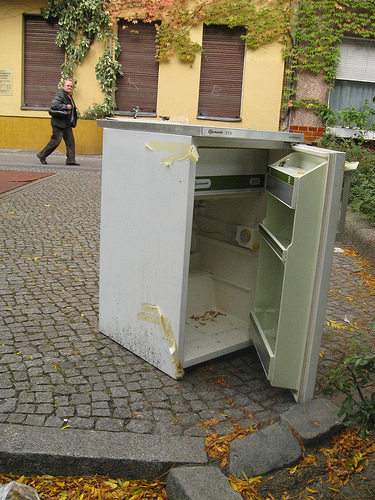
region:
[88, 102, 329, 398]
a white refridgerator on the sidewalk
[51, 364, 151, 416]
grey stone surface of the sidewalk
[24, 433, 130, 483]
grey stone curb of the sidewalk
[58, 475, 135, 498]
yellow dead fallen leaves on the street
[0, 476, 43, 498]
a clear plastic bag on the ground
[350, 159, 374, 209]
green plants growing next to the courtyard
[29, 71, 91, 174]
a man walking through the courtyard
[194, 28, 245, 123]
brown shades drawn over the window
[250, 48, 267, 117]
yellow stucco wall of a building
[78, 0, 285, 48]
plants growing on the side of the building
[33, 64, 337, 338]
a refrigerator in the open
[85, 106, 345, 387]
the refrigerator is old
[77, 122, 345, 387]
the ice box is white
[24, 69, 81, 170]
this person is walking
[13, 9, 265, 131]
three closed windows on the building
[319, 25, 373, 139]
a white curtain in the window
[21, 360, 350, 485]
the ground is made out of brick pavers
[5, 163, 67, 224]
a red outdoor carpet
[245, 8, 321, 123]
moss on the wall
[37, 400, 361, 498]
leaves on teh ground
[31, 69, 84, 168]
Man with brown pants and black jacket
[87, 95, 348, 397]
open refrigerator on sidewalk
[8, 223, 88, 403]
cobbled concrete sidewalk with loose rectangle pattern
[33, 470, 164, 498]
orange leaves covering the ground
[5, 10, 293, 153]
yellow building in background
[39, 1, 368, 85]
vines growing on building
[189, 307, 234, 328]
orange bits on bottom shelf of fridge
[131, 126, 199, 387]
tape on sides of fridge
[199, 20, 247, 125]
brown window cover with the letter b written on it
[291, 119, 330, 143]
cluster of red bricks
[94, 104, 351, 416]
the fridge is sitting by the curb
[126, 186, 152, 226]
the fridge is white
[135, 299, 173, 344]
the fridge has tape on it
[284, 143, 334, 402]
the door is open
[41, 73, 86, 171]
the lady is walking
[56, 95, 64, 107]
the coat is black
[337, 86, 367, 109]
the curtain is closed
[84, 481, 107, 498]
the leaves are yellow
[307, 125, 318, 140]
the bricks are brown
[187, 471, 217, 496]
the rock is gray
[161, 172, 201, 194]
Black and white part of a freezer.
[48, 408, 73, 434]
Black and white part of a freezer.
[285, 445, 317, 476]
Black and white part of a freezer.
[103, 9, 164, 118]
Black and white part of a freezer.